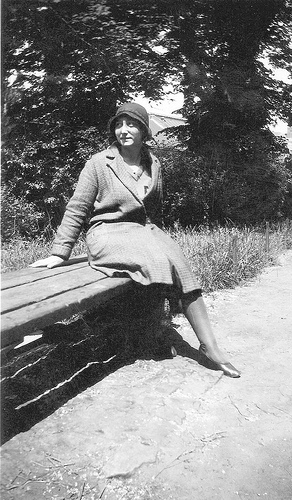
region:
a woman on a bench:
[37, 98, 246, 386]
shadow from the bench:
[1, 308, 139, 427]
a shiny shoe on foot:
[190, 345, 251, 391]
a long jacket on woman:
[43, 138, 221, 303]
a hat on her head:
[101, 93, 165, 140]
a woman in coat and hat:
[62, 67, 232, 308]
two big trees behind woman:
[13, 10, 280, 216]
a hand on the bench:
[29, 243, 86, 277]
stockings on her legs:
[174, 294, 224, 367]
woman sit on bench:
[30, 94, 246, 386]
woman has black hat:
[71, 97, 176, 210]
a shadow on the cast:
[20, 330, 130, 420]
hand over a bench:
[18, 245, 72, 280]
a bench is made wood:
[0, 247, 118, 336]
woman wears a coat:
[30, 94, 246, 385]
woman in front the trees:
[5, 2, 283, 269]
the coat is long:
[49, 146, 202, 298]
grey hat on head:
[108, 103, 151, 137]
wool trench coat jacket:
[52, 148, 201, 291]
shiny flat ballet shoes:
[200, 349, 240, 379]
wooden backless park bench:
[1, 253, 154, 381]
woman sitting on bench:
[31, 103, 241, 379]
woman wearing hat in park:
[31, 103, 242, 377]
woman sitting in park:
[33, 103, 239, 382]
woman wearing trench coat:
[29, 102, 242, 376]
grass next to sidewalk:
[169, 220, 288, 288]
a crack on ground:
[164, 435, 196, 466]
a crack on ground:
[102, 454, 135, 484]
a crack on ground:
[82, 459, 108, 477]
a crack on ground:
[134, 428, 162, 459]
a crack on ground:
[169, 402, 193, 439]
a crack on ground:
[164, 377, 181, 394]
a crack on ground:
[202, 429, 227, 451]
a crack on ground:
[237, 400, 257, 425]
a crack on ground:
[249, 396, 276, 423]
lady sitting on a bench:
[55, 87, 186, 294]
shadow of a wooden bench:
[5, 311, 146, 413]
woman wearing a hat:
[89, 91, 161, 148]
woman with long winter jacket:
[58, 92, 204, 292]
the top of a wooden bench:
[10, 210, 78, 382]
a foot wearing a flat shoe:
[192, 329, 248, 402]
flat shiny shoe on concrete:
[194, 343, 239, 381]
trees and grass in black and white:
[159, 6, 281, 247]